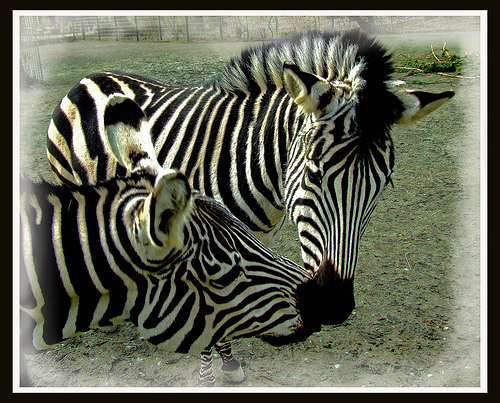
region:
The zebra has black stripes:
[270, 82, 457, 337]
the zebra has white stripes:
[300, 64, 420, 329]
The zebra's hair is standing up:
[190, 19, 424, 114]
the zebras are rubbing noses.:
[260, 235, 382, 364]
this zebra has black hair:
[202, 21, 413, 117]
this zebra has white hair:
[211, 25, 407, 133]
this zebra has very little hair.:
[0, 170, 309, 328]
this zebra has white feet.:
[180, 350, 266, 391]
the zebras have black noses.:
[261, 263, 359, 356]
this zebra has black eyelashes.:
[363, 168, 407, 200]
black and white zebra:
[52, 32, 452, 325]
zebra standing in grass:
[21, 125, 323, 395]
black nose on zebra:
[319, 271, 356, 326]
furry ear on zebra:
[137, 172, 192, 252]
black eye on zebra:
[211, 262, 241, 289]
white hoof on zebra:
[219, 364, 247, 384]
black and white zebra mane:
[211, 31, 404, 154]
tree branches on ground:
[401, 44, 463, 80]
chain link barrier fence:
[63, 19, 356, 37]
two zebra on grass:
[19, 32, 451, 388]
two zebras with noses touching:
[65, 48, 431, 385]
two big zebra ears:
[99, 98, 194, 239]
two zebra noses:
[252, 226, 376, 358]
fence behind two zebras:
[69, 20, 269, 48]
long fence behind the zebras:
[41, 19, 395, 54]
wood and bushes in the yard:
[408, 47, 468, 71]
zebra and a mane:
[101, 39, 452, 211]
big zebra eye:
[206, 245, 248, 307]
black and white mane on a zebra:
[218, 34, 406, 114]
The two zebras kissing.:
[32, 26, 454, 360]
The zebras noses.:
[290, 260, 359, 332]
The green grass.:
[401, 178, 497, 390]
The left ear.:
[130, 173, 202, 268]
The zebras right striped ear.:
[271, 60, 456, 132]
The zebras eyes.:
[295, 145, 396, 197]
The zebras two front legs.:
[201, 347, 256, 387]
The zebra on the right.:
[52, 57, 402, 308]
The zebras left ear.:
[102, 88, 154, 171]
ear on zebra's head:
[132, 168, 192, 257]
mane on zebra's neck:
[220, 28, 397, 132]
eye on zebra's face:
[304, 163, 321, 183]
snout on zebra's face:
[312, 261, 354, 330]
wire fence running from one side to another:
[17, 16, 478, 41]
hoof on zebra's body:
[222, 364, 244, 381]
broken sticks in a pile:
[390, 41, 478, 79]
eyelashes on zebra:
[389, 175, 395, 190]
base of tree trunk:
[347, 15, 378, 32]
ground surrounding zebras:
[21, 17, 481, 385]